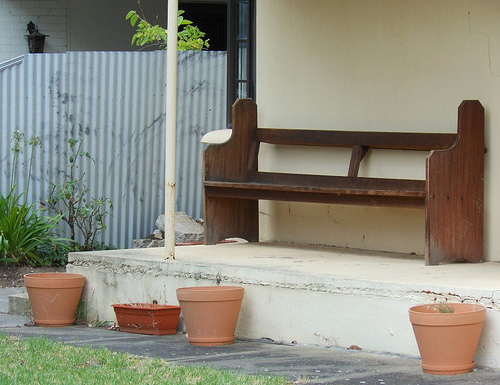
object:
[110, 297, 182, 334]
rectangular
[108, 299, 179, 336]
pot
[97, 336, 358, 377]
sidewalk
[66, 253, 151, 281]
edge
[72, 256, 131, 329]
stoop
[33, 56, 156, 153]
fence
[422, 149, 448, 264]
bench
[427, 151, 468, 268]
wooden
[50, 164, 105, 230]
garden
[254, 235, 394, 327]
pad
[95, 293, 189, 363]
teracotta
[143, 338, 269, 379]
ground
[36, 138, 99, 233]
leaves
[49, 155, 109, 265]
plant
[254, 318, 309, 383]
wall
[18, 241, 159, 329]
ground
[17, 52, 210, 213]
wall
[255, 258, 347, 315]
step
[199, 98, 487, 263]
wooden bench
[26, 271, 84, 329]
terra cotta pot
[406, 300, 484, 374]
terra cotta planter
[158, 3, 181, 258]
white pole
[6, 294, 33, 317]
edge of stoop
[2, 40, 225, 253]
tall fence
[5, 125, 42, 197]
skinny sapling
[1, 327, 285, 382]
patch of grass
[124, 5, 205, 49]
long leaves plant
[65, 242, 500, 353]
cement pad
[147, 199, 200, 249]
large rock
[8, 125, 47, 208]
thin trees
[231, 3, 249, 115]
glass window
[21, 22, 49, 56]
planter pot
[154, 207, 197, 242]
gray racks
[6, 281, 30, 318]
white stone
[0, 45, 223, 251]
metal fence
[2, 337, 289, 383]
green grass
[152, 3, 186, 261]
pole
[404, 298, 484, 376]
orange pot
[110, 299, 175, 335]
orange planter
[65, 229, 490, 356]
concrete sidewalk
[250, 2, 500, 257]
beige wall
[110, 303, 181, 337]
dark pot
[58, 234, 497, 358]
porch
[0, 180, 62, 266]
plant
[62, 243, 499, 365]
grass walkway